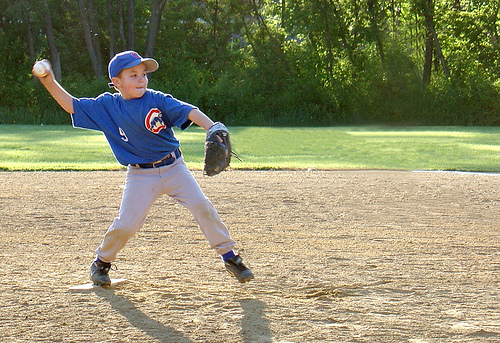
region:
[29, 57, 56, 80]
balls is held in hand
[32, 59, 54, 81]
hand holds ball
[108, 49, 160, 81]
hat is worn on head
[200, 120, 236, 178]
baseball gloves is worn on hand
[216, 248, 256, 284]
foot is off ground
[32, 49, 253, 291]
pitcher begins to throw ball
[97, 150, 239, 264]
pants are worn by child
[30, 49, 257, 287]
pitcher stands on plate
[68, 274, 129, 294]
plate is underneath pitcher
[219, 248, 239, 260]
sock is worn by pitcher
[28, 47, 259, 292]
a boy is throwing a baseball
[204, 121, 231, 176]
a dark brown baseball glove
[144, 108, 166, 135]
a logo on a boy's jersey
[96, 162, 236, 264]
a boy's long baseball pants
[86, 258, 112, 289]
the shoe of a boy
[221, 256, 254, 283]
the shoe of a boy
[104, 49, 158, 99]
head of a boy wearing a hat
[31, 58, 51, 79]
baseball is in a boy's hand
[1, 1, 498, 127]
a dense thicket of foliage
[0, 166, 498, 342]
dirt is covering the ground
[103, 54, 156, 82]
boy has blue hat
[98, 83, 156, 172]
red and blue shirt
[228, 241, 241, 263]
boy has blue socks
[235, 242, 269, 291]
boy has grey shoes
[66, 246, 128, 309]
boy stands on pitcher's mound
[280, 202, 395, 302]
infield is light brown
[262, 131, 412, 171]
green grass beyond infield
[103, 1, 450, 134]
thick forest behind grass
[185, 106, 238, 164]
boy has black glove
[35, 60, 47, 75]
A ball in the hand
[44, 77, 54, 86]
Hand held high up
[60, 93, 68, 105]
Arm swinging to throw a ball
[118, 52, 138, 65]
A blue cap on the head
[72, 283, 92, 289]
The foot marker on the ground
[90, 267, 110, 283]
Shoe on the foot marker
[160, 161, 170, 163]
A belt on the waist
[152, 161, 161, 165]
The buckle of the belt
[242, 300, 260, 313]
Shadow of raised foot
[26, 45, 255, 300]
this is a person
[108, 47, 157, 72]
this is a cap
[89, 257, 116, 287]
this is a shoe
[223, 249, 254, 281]
this is a shoe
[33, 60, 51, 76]
this is a ball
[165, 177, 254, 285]
this is a persons leg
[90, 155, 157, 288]
this is a persons leg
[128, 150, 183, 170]
this is a belt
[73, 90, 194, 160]
this is a blue tshirt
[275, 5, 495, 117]
this is green vegetation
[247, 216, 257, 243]
sitting on a rock.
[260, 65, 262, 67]
A green leaf on a plant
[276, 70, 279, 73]
A green leaf on a plant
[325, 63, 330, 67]
A green leaf on a plant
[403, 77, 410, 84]
A green leaf on a plant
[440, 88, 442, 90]
A green leaf on a plant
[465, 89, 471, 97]
A green leaf on a plant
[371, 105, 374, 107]
A green leaf on a plant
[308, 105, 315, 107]
A green leaf on a plant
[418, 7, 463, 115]
A tree in the woods.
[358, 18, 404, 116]
A tree in the woods.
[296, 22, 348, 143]
A tree in the woods.